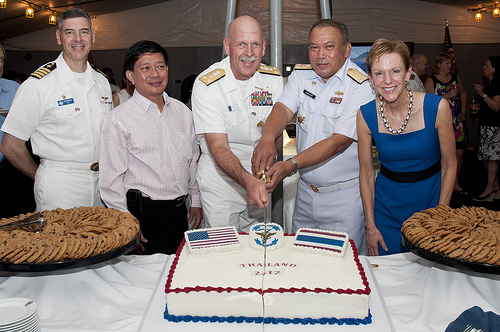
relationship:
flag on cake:
[291, 226, 350, 255] [161, 220, 374, 323]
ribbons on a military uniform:
[249, 90, 274, 105] [200, 61, 271, 230]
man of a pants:
[250, 17, 367, 252] [281, 172, 360, 251]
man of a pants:
[188, 12, 288, 230] [194, 131, 270, 231]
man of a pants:
[0, 7, 121, 216] [24, 154, 103, 211]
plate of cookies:
[399, 227, 499, 277] [401, 204, 498, 261]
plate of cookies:
[399, 227, 499, 277] [3, 206, 138, 263]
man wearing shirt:
[98, 39, 202, 254] [102, 86, 203, 219]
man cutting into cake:
[250, 14, 370, 249] [161, 220, 374, 323]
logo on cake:
[247, 217, 285, 249] [161, 221, 371, 277]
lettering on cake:
[241, 247, 298, 284] [161, 220, 374, 323]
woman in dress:
[356, 37, 457, 254] [359, 92, 443, 254]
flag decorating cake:
[185, 225, 239, 251] [161, 220, 374, 323]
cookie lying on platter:
[24, 245, 47, 263] [1, 231, 140, 274]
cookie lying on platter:
[40, 219, 66, 235] [1, 231, 140, 274]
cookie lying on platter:
[447, 248, 466, 259] [383, 196, 496, 301]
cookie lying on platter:
[468, 216, 484, 226] [383, 196, 496, 301]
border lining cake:
[163, 230, 371, 295] [161, 220, 374, 323]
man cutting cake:
[188, 12, 282, 230] [161, 220, 374, 323]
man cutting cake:
[250, 14, 370, 249] [161, 220, 374, 323]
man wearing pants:
[98, 39, 202, 254] [106, 184, 167, 245]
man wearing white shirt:
[188, 12, 288, 230] [195, 63, 267, 156]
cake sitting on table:
[166, 213, 381, 328] [9, 247, 164, 329]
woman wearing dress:
[356, 37, 457, 254] [359, 92, 443, 254]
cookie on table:
[24, 245, 47, 263] [0, 241, 497, 328]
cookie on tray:
[447, 248, 466, 259] [384, 197, 497, 274]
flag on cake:
[183, 225, 239, 251] [181, 220, 358, 330]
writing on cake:
[239, 258, 298, 274] [161, 220, 374, 323]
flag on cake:
[291, 228, 350, 250] [161, 220, 374, 323]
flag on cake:
[183, 225, 239, 251] [161, 220, 374, 323]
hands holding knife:
[239, 138, 299, 213] [256, 166, 271, 252]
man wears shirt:
[0, 7, 121, 216] [4, 58, 115, 155]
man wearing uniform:
[0, 7, 121, 216] [1, 50, 115, 212]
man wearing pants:
[9, 8, 123, 231] [11, 10, 93, 198]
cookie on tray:
[24, 245, 47, 263] [1, 237, 144, 277]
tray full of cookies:
[4, 248, 137, 276] [0, 203, 144, 277]